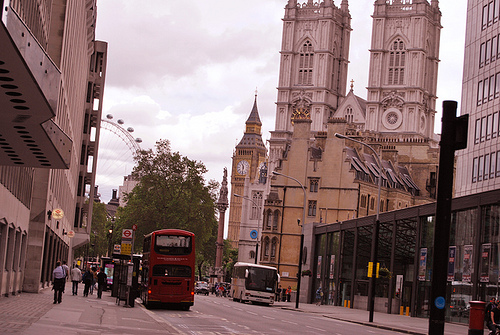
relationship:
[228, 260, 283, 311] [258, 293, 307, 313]
bus at curb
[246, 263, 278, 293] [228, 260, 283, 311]
windshield of bus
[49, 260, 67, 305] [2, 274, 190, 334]
pedestrian on sidewalk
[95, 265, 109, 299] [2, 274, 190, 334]
pedestrian on sidewalk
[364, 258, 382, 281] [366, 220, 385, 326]
sign on pole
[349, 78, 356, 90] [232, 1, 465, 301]
steeple on building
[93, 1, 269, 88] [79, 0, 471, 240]
clouds in sky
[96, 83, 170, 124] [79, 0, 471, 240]
clouds in sky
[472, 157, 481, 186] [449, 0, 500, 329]
windows of building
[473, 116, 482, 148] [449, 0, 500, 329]
windows of building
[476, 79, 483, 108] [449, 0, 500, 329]
windows of building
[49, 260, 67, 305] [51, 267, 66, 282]
pedestrian in shirt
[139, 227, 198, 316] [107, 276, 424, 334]
bus alongside street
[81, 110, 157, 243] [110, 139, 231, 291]
ferris wheel behind tree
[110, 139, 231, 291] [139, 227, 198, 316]
tree behind bus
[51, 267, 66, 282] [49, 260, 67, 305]
shirt on pedestrian